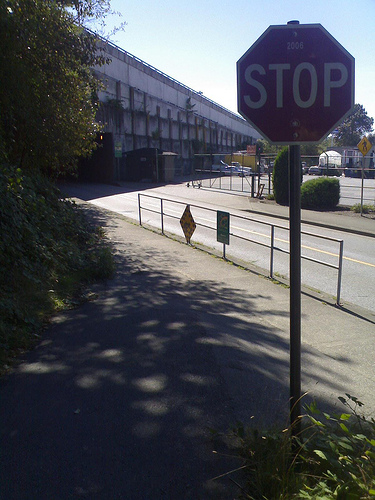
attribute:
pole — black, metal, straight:
[283, 139, 310, 466]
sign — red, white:
[233, 22, 357, 161]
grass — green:
[1, 200, 123, 377]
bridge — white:
[73, 19, 271, 185]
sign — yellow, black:
[353, 135, 373, 158]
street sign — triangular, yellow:
[177, 206, 198, 242]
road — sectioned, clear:
[60, 177, 374, 319]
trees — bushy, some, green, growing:
[2, 1, 129, 403]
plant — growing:
[200, 380, 371, 499]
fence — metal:
[135, 193, 344, 311]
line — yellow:
[73, 180, 373, 266]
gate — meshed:
[188, 150, 278, 203]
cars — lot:
[215, 157, 249, 174]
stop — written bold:
[238, 60, 350, 118]